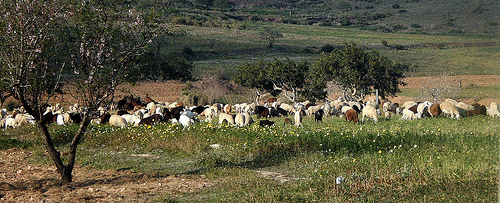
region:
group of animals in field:
[143, 61, 447, 148]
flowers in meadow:
[276, 122, 336, 176]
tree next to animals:
[23, 21, 151, 183]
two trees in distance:
[261, 43, 385, 88]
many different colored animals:
[171, 86, 313, 145]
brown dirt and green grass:
[135, 143, 242, 199]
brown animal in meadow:
[334, 106, 361, 131]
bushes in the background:
[164, 9, 249, 38]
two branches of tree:
[18, 111, 98, 176]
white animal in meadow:
[228, 107, 255, 133]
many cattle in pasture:
[17, 54, 474, 174]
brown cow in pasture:
[342, 105, 366, 133]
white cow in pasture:
[165, 108, 206, 135]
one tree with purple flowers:
[4, 5, 172, 200]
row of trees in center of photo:
[187, 47, 422, 108]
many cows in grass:
[0, 87, 487, 159]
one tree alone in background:
[251, 15, 286, 67]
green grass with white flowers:
[70, 20, 324, 197]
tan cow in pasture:
[420, 67, 485, 137]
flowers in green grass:
[110, 107, 450, 199]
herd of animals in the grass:
[8, 88, 495, 130]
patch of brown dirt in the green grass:
[3, 151, 183, 201]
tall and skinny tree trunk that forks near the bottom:
[13, 76, 100, 184]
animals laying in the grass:
[7, 86, 488, 126]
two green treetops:
[227, 46, 410, 100]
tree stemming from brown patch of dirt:
[0, 1, 138, 190]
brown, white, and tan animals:
[405, 99, 499, 116]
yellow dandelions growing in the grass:
[125, 123, 283, 150]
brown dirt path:
[39, 74, 498, 99]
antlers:
[276, 84, 303, 105]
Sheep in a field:
[2, 95, 499, 130]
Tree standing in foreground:
[1, 2, 191, 187]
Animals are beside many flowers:
[92, 125, 498, 156]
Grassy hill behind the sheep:
[161, 24, 499, 61]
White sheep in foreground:
[178, 115, 198, 130]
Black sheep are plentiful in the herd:
[313, 108, 328, 122]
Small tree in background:
[259, 27, 284, 49]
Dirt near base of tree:
[3, 168, 197, 201]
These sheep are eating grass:
[393, 98, 497, 126]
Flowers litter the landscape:
[326, 129, 499, 186]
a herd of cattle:
[3, 72, 494, 154]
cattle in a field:
[3, 8, 493, 197]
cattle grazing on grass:
[8, 3, 490, 199]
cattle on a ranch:
[7, 7, 494, 199]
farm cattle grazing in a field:
[4, 6, 491, 198]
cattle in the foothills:
[6, 5, 498, 196]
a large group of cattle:
[3, 2, 498, 200]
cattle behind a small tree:
[4, 7, 175, 195]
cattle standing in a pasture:
[8, 5, 498, 197]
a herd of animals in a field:
[5, 5, 498, 199]